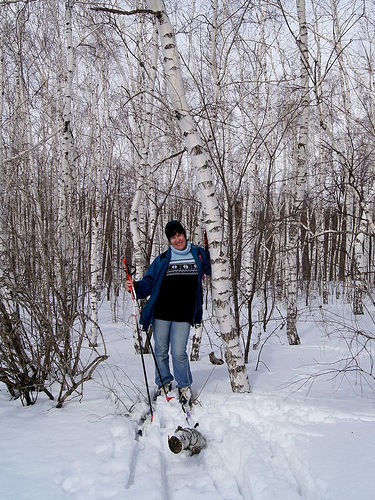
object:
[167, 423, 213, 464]
tree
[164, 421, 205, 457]
log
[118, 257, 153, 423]
ski poles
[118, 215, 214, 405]
woman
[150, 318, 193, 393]
blue jeans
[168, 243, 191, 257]
turtle neck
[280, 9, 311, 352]
trees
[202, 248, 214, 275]
arm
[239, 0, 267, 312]
tree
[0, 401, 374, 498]
snow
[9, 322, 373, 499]
ground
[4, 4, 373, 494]
picture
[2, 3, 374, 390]
wooded area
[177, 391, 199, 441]
skis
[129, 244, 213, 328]
coat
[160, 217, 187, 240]
hair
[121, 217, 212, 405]
she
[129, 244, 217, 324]
sweater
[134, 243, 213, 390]
clothing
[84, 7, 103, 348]
trees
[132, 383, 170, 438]
skis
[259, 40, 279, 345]
tree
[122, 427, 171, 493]
tracks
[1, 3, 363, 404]
several trees